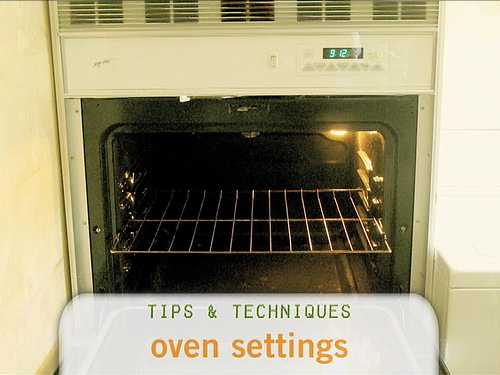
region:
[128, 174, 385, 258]
wire grill in the oven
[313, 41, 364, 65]
clock in the oven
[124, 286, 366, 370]
message on the screen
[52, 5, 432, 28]
vent on the oven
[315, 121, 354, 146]
light in the oven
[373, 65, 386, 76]
button on the oven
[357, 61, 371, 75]
button on the oven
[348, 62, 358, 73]
button on the oven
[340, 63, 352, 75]
button on the oven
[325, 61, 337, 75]
button on the oven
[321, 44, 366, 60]
digital display on an oven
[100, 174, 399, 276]
silver metal rack of an oven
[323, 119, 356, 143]
light on the inside of an oven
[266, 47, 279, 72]
white light switch on an oven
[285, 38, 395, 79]
digital control panel on an oven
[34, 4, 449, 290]
white oven built into the wall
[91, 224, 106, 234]
silver screw in an oven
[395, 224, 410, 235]
silver screw in an oven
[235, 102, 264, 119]
silver latch on an oven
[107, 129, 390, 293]
cooking cavity in an oven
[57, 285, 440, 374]
text is overlayed on the picture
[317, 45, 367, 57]
clock is on front of oven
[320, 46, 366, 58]
clock is digital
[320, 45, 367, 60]
clock shows time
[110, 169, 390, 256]
rack is empty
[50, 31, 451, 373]
oven door is open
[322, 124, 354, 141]
oven light is on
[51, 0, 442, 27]
vent is on front of oven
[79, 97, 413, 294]
oven is made of metal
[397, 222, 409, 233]
screw is on front of oven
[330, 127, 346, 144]
light in the oven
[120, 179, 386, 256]
rack in the oven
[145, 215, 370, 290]
bottom of the oven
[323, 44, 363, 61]
digital clock on the oven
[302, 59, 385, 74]
control buttons on the oven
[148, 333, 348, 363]
orange lettering on white background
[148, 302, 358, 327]
green text on white background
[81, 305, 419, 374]
open door of the oven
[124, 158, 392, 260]
adjustment brackets for the oven rack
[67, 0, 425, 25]
venting above the oven